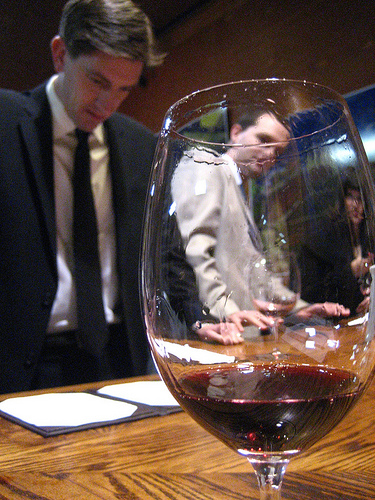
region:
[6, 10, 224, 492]
man examining a menu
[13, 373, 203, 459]
menu on the table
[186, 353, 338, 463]
liquid in a glass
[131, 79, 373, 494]
glass with liquid in it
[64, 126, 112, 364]
tie on the man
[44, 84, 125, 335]
shirt on the man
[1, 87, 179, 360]
jacket on the man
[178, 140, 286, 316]
jacket on the man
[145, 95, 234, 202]
image on the wall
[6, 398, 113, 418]
paper menu printed on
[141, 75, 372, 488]
Wine glass on table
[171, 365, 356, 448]
Red wine in glass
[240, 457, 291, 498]
Stem of wine glass on table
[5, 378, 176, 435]
Open folder on table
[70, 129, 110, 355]
Tie around man's neck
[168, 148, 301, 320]
Tan suit coat on man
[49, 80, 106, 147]
Sharp white collar on shirt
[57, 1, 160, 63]
Brown hair on man's head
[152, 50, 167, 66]
Flyaway section of hair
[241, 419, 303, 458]
Reflections in wine glass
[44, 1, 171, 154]
a man looking down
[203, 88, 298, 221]
a man looking down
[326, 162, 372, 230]
a woman looking to the side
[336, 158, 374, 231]
a woman through the side of a wine glass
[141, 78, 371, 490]
a glass of red wine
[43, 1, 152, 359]
a man wearing a black tie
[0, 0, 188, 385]
a man wearing a black suit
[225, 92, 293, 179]
the head of a man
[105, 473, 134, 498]
dark brown wood grain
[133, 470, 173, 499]
dark brown wood grain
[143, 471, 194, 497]
dark brown wood grain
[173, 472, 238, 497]
dark brown wood grain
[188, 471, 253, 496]
dark brown wood grain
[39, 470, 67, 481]
dark brown wood grain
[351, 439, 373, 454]
dark brown wood grain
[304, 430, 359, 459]
dark brown wood grain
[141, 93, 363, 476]
a wine glass with some wine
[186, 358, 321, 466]
a little bit of wine in a glass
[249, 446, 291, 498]
the handle of a wine glass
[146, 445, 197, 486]
a brown wooden tabletop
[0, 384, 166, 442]
an open document of some sorts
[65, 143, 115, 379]
a mans black tie that is tied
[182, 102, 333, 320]
a full grown man in a suit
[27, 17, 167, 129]
the head of an adult male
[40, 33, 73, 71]
the ear of an adult male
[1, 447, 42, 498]
a stained wood finish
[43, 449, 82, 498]
a stained wood finish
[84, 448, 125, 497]
a stained wood finish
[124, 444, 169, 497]
a stained wood finish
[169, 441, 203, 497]
a stained wood finish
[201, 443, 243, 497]
a stained wood finish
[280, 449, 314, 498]
a stained wood finish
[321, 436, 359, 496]
a stained wood finish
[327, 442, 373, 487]
a stained wood finish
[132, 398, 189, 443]
a stained wood finish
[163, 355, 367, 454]
wine in wine glass